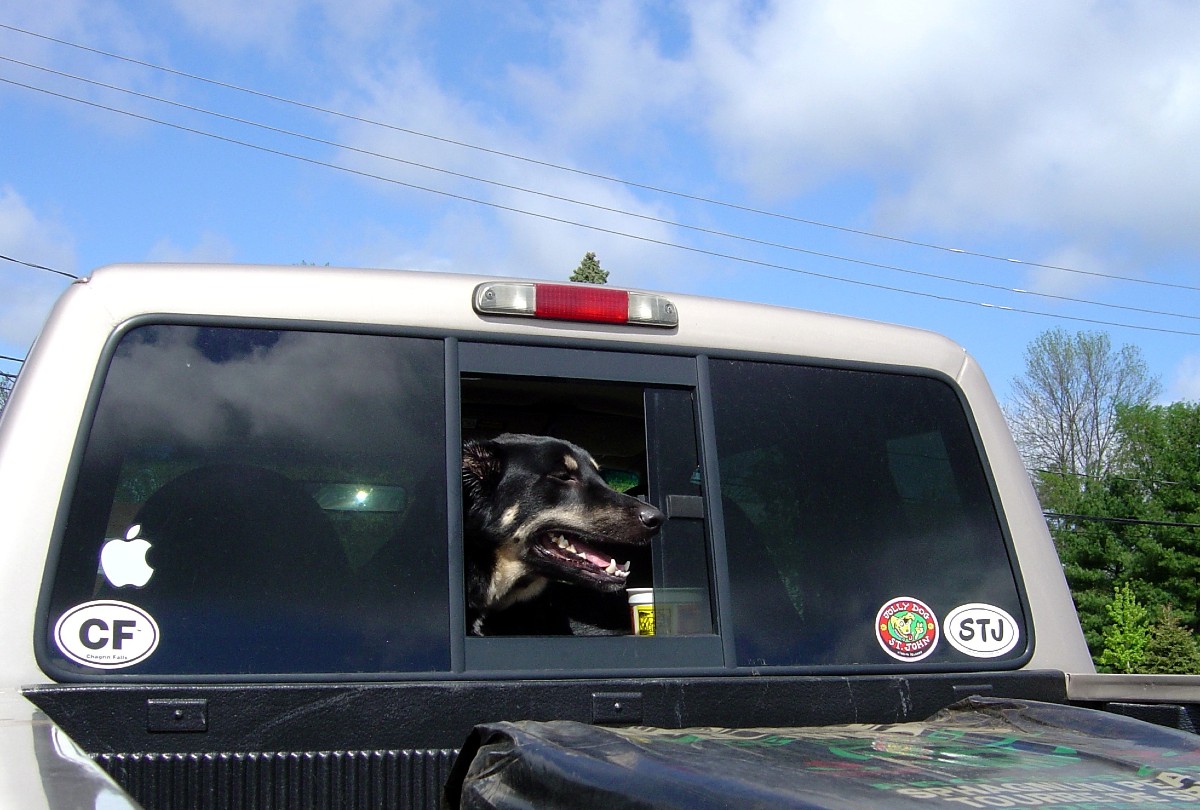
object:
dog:
[462, 432, 665, 638]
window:
[31, 323, 1037, 679]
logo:
[52, 599, 163, 670]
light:
[473, 282, 680, 328]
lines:
[0, 30, 1200, 334]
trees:
[1001, 325, 1200, 684]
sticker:
[943, 602, 1021, 658]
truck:
[0, 263, 1200, 809]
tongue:
[569, 536, 626, 572]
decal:
[100, 523, 155, 587]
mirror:
[288, 481, 410, 512]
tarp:
[445, 695, 1200, 808]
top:
[35, 263, 988, 381]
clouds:
[0, 0, 1200, 525]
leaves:
[1100, 576, 1145, 670]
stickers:
[873, 596, 1019, 663]